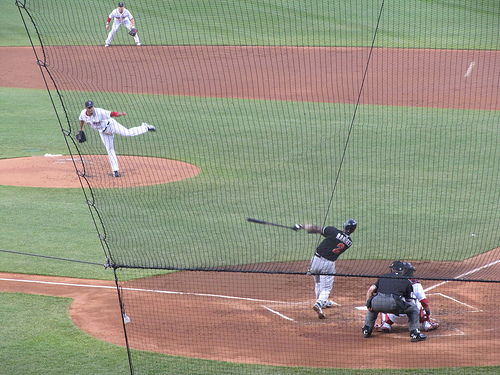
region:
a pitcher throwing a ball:
[72, 98, 157, 182]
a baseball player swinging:
[247, 215, 356, 320]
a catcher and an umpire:
[363, 261, 438, 342]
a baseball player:
[102, 3, 143, 47]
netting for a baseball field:
[17, 1, 499, 373]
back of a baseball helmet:
[344, 220, 359, 235]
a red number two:
[331, 242, 342, 257]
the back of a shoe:
[360, 326, 370, 337]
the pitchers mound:
[0, 155, 199, 187]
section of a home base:
[355, 303, 370, 311]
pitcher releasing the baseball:
[73, 100, 157, 177]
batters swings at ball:
[243, 215, 358, 320]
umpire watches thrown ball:
[361, 260, 426, 342]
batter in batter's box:
[243, 213, 359, 326]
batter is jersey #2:
[313, 225, 352, 260]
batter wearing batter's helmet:
[341, 216, 352, 231]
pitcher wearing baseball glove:
[75, 127, 85, 140]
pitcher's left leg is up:
[113, 121, 153, 133]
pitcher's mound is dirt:
[0, 153, 196, 185]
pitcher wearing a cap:
[84, 98, 92, 108]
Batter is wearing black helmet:
[302, 217, 357, 312]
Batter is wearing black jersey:
[300, 211, 355, 316]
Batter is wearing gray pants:
[302, 215, 357, 325]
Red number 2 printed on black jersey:
[328, 238, 347, 255]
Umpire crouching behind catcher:
[359, 261, 431, 346]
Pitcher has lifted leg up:
[70, 100, 160, 175]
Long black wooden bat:
[247, 215, 302, 236]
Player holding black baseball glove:
[102, 0, 144, 45]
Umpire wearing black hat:
[361, 258, 428, 341]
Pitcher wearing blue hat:
[75, 95, 158, 178]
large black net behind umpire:
[15, 0, 497, 373]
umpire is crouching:
[358, 257, 425, 344]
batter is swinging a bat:
[247, 215, 360, 319]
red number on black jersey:
[330, 242, 347, 258]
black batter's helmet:
[343, 216, 356, 233]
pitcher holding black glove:
[73, 131, 88, 144]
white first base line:
[421, 258, 499, 298]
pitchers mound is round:
[3, 153, 199, 195]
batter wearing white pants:
[311, 253, 343, 305]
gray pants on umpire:
[365, 291, 427, 330]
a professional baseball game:
[6, 3, 493, 368]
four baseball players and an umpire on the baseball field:
[4, 1, 494, 368]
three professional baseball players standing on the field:
[73, 1, 358, 321]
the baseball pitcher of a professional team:
[74, 100, 158, 179]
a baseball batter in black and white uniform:
[244, 215, 358, 320]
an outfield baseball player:
[102, 1, 139, 47]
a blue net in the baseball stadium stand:
[15, 0, 496, 372]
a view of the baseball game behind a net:
[71, 1, 497, 371]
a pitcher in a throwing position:
[74, 100, 158, 179]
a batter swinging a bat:
[245, 215, 358, 321]